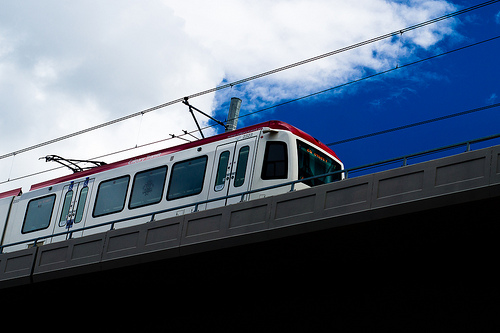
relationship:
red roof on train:
[118, 117, 309, 144] [31, 109, 356, 222]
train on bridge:
[2, 120, 346, 253] [0, 153, 495, 310]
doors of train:
[205, 136, 257, 209] [2, 120, 346, 253]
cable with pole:
[7, 77, 258, 180] [219, 85, 246, 139]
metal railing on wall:
[0, 134, 500, 248] [20, 213, 283, 279]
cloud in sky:
[0, 0, 460, 197] [2, 1, 499, 201]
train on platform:
[2, 120, 346, 253] [1, 146, 491, 286]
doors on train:
[215, 141, 286, 215] [26, 117, 361, 228]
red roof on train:
[118, 117, 309, 144] [2, 120, 346, 253]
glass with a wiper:
[296, 138, 342, 184] [308, 153, 334, 181]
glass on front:
[296, 138, 342, 184] [280, 119, 351, 203]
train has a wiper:
[2, 120, 346, 253] [308, 153, 334, 181]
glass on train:
[296, 138, 342, 184] [2, 120, 346, 253]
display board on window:
[299, 143, 331, 167] [300, 142, 337, 183]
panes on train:
[71, 139, 208, 233] [8, 84, 380, 277]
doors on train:
[57, 177, 94, 243] [2, 120, 346, 253]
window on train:
[292, 140, 344, 188] [0, 94, 354, 279]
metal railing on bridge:
[9, 129, 492, 274] [0, 148, 474, 322]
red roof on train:
[118, 117, 309, 144] [248, 121, 343, 200]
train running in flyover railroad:
[2, 104, 358, 261] [0, 137, 497, 291]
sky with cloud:
[2, 1, 499, 201] [4, 4, 463, 174]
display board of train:
[299, 143, 336, 168] [2, 104, 358, 261]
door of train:
[43, 180, 98, 240] [64, 97, 361, 261]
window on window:
[169, 153, 204, 196] [130, 168, 163, 207]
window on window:
[169, 153, 204, 196] [94, 175, 126, 213]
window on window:
[169, 153, 204, 196] [22, 195, 53, 231]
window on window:
[169, 153, 204, 196] [74, 183, 86, 225]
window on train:
[169, 153, 204, 196] [2, 120, 346, 253]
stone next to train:
[2, 147, 500, 287] [2, 120, 346, 253]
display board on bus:
[299, 143, 331, 167] [1, 115, 347, 245]